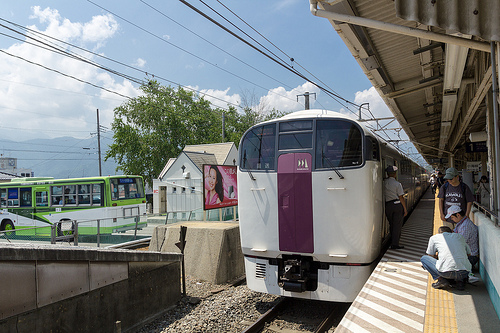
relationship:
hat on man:
[445, 203, 465, 216] [444, 205, 481, 268]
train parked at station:
[238, 113, 428, 313] [207, 7, 496, 331]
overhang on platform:
[320, 0, 478, 175] [330, 171, 498, 332]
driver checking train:
[383, 166, 414, 249] [238, 113, 428, 313]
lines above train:
[1, 1, 400, 144] [238, 113, 428, 313]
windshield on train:
[243, 120, 363, 172] [238, 113, 428, 313]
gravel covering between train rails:
[162, 281, 330, 332] [244, 297, 340, 332]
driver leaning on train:
[383, 166, 414, 249] [238, 113, 428, 313]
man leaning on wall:
[440, 168, 478, 236] [456, 192, 499, 307]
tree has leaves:
[107, 79, 278, 189] [115, 85, 265, 180]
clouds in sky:
[1, 15, 408, 164] [1, 3, 431, 200]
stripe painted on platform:
[424, 175, 459, 333] [330, 171, 498, 332]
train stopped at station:
[238, 113, 428, 313] [207, 7, 496, 331]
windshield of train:
[243, 120, 363, 172] [238, 113, 428, 313]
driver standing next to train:
[383, 166, 414, 249] [238, 113, 428, 313]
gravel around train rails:
[162, 281, 330, 332] [244, 297, 340, 332]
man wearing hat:
[440, 168, 478, 236] [441, 166, 463, 179]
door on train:
[276, 152, 314, 253] [238, 113, 428, 313]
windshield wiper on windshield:
[242, 139, 345, 185] [243, 120, 363, 172]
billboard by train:
[199, 155, 243, 210] [238, 113, 428, 313]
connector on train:
[279, 258, 313, 291] [238, 113, 428, 313]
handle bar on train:
[246, 246, 349, 262] [238, 113, 428, 313]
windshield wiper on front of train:
[242, 139, 345, 185] [238, 113, 428, 313]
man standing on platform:
[437, 168, 475, 231] [330, 171, 498, 332]